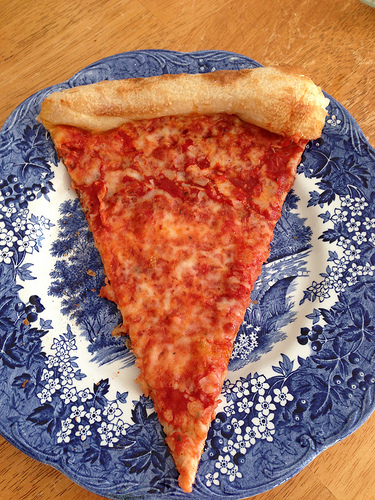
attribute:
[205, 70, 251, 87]
spot — dark brown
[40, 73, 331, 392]
pizza — cheese, yellow, red, orange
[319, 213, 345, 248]
leaves — blue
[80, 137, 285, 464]
pizza — triangle shaped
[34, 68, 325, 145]
crust — golden, Brown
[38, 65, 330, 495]
pizza — big, well cooked, sliced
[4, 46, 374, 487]
design — floral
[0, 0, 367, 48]
table —  light brown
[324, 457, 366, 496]
table — brown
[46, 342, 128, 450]
flower — white, drawing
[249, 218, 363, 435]
plate — blue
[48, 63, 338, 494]
pizza slice — sliced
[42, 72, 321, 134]
crust — light brown, thick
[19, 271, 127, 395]
crumbs — pizza crumbs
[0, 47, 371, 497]
plate — blue, white, decoration, designed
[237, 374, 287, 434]
flowers — drawings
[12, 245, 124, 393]
design — white, flower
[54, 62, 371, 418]
plate — blue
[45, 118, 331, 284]
pizza — red, light brown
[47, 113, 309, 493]
sauce — orange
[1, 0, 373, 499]
table — wooden, wood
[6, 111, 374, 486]
flower design — white